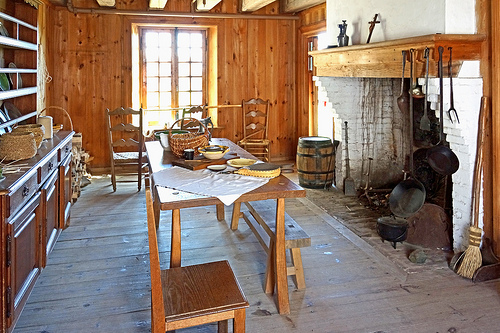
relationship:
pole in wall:
[291, 22, 299, 157] [53, 5, 300, 173]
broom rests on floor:
[460, 90, 490, 281] [11, 169, 499, 332]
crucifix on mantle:
[365, 9, 381, 44] [307, 31, 483, 80]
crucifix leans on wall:
[365, 9, 381, 44] [299, 0, 500, 258]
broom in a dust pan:
[460, 90, 490, 281] [448, 233, 499, 285]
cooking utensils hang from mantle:
[390, 47, 454, 217] [307, 31, 483, 80]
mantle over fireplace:
[307, 31, 483, 80] [316, 76, 457, 245]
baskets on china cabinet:
[1, 106, 74, 164] [1, 2, 76, 331]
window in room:
[140, 27, 208, 123] [1, 0, 499, 331]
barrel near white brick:
[296, 137, 336, 190] [307, 79, 386, 181]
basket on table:
[167, 116, 213, 156] [143, 135, 305, 318]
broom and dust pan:
[460, 90, 490, 281] [448, 233, 499, 285]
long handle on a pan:
[409, 51, 415, 182] [391, 51, 425, 217]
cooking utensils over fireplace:
[390, 47, 454, 217] [316, 76, 457, 245]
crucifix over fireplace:
[365, 9, 381, 44] [316, 76, 457, 245]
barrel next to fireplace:
[296, 137, 336, 190] [316, 76, 457, 245]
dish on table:
[230, 154, 258, 171] [143, 135, 305, 318]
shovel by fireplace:
[342, 118, 358, 198] [316, 76, 457, 245]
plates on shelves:
[1, 61, 25, 88] [5, 2, 44, 158]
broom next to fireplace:
[460, 90, 490, 281] [316, 76, 457, 245]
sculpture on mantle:
[338, 22, 354, 51] [307, 31, 483, 80]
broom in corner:
[460, 90, 490, 281] [447, 5, 499, 297]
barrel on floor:
[296, 137, 336, 190] [11, 169, 499, 332]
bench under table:
[229, 200, 307, 296] [143, 135, 305, 318]